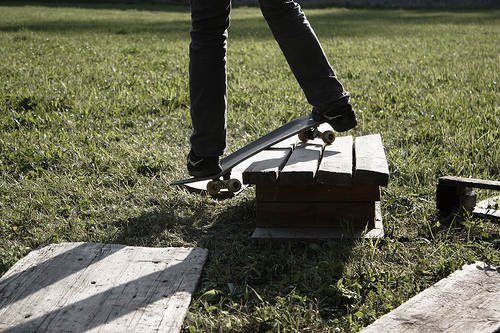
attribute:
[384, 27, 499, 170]
grass field — green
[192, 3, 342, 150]
denim — black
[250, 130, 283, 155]
skateboard — black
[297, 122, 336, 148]
wheels — yellow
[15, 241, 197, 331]
wooden plank — gray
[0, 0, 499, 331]
grass field — green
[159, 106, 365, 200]
skateboard — slatted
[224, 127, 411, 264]
base — wooden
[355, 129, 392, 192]
wood — stacked, plank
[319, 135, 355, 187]
wood — stacked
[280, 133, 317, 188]
wood — stacked, plank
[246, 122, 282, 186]
wood — stacked, plank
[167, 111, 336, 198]
skating board — black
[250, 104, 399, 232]
plank — old, wood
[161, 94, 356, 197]
skateboard — black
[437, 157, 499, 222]
wood — old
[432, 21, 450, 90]
grass — green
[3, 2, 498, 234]
grassy field — green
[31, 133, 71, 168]
grass — green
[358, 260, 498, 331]
wooden plank — gray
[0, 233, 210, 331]
wooden plank — gray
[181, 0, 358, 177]
jeans — black, dark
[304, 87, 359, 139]
sneaker — black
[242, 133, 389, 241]
timber — wooden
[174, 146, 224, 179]
sneaker — black, puma, cat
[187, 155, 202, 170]
logo — white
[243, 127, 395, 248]
wood — stacked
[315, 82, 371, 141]
shoe — skating, black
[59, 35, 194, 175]
field — green, grass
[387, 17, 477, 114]
field — grass, green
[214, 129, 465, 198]
step — small, homemade, performance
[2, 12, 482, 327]
area — grassy